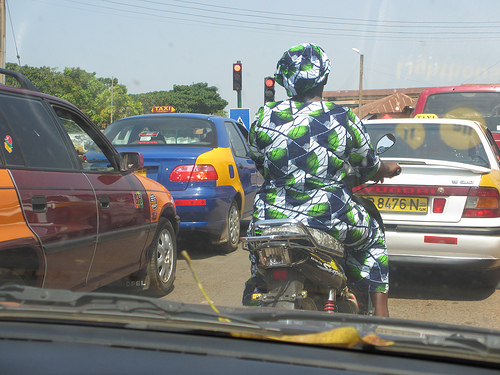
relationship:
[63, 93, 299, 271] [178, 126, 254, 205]
car with spots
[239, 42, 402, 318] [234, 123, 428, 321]
person sitting on moped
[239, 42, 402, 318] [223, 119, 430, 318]
person riding motorcycle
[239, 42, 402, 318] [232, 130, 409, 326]
person on motorbike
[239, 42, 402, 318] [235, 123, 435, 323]
person riding motorbike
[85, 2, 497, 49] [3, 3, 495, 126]
wires in sky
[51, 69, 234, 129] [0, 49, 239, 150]
leaves on trees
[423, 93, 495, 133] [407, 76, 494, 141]
window on truck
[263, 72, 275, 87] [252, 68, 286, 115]
circles on lights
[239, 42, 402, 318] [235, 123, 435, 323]
person sitting on motorbike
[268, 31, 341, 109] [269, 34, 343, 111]
cloth covering head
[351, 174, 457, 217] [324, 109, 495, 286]
plate on car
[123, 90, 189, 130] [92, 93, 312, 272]
sign on car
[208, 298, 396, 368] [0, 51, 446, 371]
leaf on windshield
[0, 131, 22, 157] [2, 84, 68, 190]
decal on window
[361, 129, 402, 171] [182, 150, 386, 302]
mirror on motorcycle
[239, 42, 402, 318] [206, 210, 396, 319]
person on motorcycle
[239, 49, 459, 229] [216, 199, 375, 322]
person on moped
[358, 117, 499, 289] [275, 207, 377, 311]
cab by moped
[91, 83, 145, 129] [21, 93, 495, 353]
trees above cars